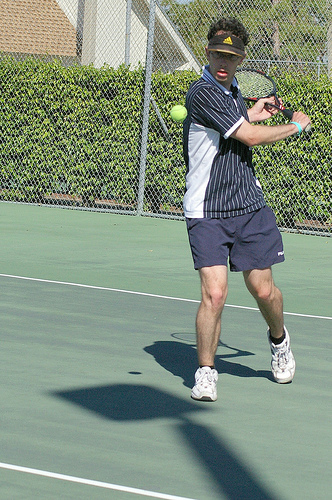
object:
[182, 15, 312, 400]
man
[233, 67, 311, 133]
racket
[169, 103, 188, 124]
tennis ball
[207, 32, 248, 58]
visor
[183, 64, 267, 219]
shirt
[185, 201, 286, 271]
shorts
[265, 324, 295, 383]
shoe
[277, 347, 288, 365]
laces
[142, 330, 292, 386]
shadow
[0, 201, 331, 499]
court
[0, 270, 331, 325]
line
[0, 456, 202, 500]
line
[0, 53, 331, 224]
bush hedge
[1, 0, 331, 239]
fence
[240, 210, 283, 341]
leg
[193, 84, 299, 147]
arm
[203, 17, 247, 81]
head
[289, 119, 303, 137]
bracelet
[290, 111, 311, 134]
hand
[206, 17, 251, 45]
hair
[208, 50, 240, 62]
glasses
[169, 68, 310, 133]
tennis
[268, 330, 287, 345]
sock